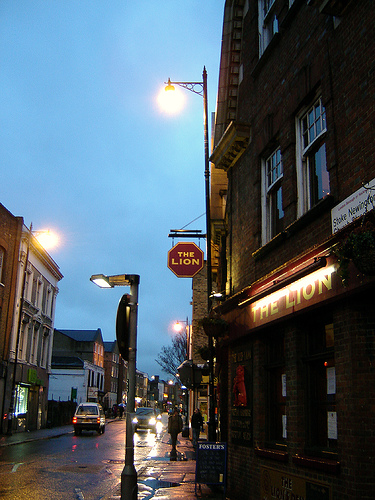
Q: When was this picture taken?
A: Dusk.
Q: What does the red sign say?
A: The lion.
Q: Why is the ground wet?
A: Rain.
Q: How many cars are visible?
A: Two.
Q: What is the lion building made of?
A: Brick.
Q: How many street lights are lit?
A: Four.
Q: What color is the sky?
A: Blue.